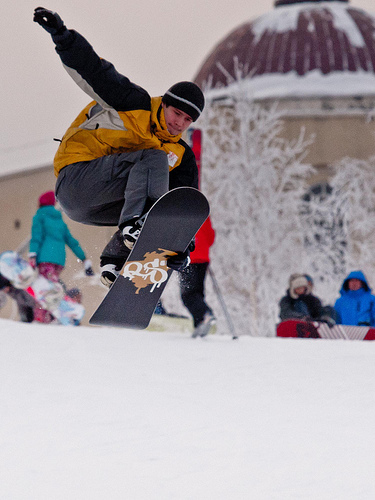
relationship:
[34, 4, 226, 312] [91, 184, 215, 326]
man on snowboard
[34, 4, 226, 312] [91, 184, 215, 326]
man holds snowboard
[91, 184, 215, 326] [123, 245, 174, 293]
snowboard has logo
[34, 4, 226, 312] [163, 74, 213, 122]
man wears cap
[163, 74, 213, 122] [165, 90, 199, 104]
cap has stripe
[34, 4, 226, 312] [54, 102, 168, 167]
man wears jacket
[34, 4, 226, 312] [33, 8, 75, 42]
man wears glove